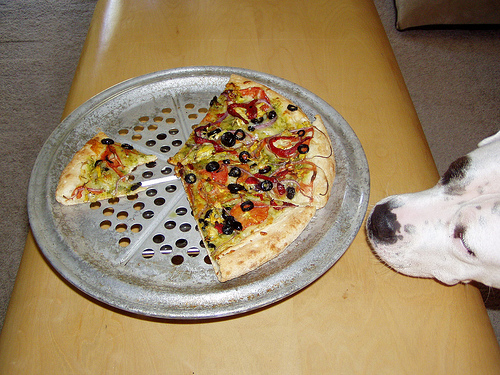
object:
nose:
[366, 201, 398, 240]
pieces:
[175, 168, 332, 283]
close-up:
[19, 53, 499, 343]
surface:
[0, 0, 499, 374]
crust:
[306, 114, 335, 161]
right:
[417, 2, 499, 372]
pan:
[27, 65, 370, 321]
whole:
[142, 136, 156, 153]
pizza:
[55, 132, 159, 204]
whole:
[166, 129, 183, 136]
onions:
[283, 177, 306, 189]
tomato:
[227, 201, 270, 226]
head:
[363, 130, 498, 290]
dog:
[365, 132, 499, 288]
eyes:
[456, 225, 476, 255]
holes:
[170, 254, 185, 266]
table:
[0, 1, 499, 374]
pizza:
[180, 165, 312, 274]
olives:
[258, 177, 275, 194]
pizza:
[177, 166, 314, 283]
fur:
[459, 156, 470, 167]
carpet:
[0, 0, 98, 335]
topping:
[227, 167, 243, 177]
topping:
[220, 130, 237, 146]